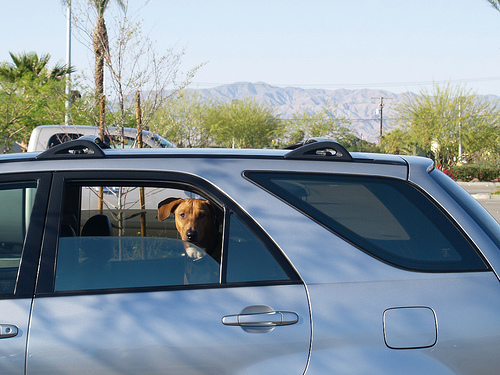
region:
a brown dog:
[158, 187, 218, 261]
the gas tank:
[379, 305, 441, 357]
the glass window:
[78, 239, 195, 282]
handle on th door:
[220, 308, 294, 338]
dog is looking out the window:
[153, 192, 226, 253]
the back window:
[335, 187, 431, 237]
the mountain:
[268, 85, 338, 115]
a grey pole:
[448, 102, 467, 153]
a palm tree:
[90, 18, 117, 98]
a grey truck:
[33, 118, 79, 139]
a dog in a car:
[22, 70, 393, 370]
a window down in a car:
[18, 47, 347, 372]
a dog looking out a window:
[50, 121, 454, 370]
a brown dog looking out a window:
[19, 97, 314, 369]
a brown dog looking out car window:
[39, 107, 303, 312]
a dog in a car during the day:
[51, 72, 497, 356]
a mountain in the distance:
[186, 29, 471, 156]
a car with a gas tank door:
[293, 217, 494, 369]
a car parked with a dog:
[35, 92, 472, 371]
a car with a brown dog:
[72, 85, 493, 349]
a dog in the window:
[54, 87, 301, 259]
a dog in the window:
[121, 156, 217, 353]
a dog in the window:
[71, 113, 308, 368]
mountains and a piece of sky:
[147, 53, 401, 135]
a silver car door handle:
[189, 301, 301, 361]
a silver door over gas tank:
[361, 300, 448, 374]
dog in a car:
[128, 180, 233, 320]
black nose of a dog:
[174, 225, 201, 250]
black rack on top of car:
[35, 108, 370, 177]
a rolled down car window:
[0, 198, 217, 326]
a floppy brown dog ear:
[144, 193, 189, 234]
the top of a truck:
[10, 109, 177, 176]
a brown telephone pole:
[341, 93, 396, 148]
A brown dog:
[136, 172, 233, 304]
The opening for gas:
[349, 268, 458, 363]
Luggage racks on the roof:
[39, 132, 370, 179]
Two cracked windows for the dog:
[46, 184, 224, 296]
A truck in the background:
[5, 105, 322, 285]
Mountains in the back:
[90, 68, 497, 158]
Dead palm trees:
[79, 21, 174, 147]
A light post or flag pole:
[65, 18, 88, 138]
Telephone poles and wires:
[353, 88, 461, 168]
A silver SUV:
[7, 160, 492, 372]